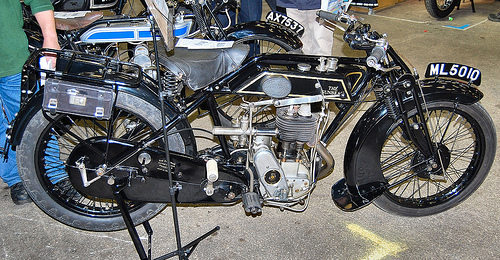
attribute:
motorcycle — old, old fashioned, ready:
[21, 3, 496, 256]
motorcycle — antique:
[39, 15, 485, 241]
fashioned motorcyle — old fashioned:
[14, 10, 489, 246]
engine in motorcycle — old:
[221, 101, 357, 215]